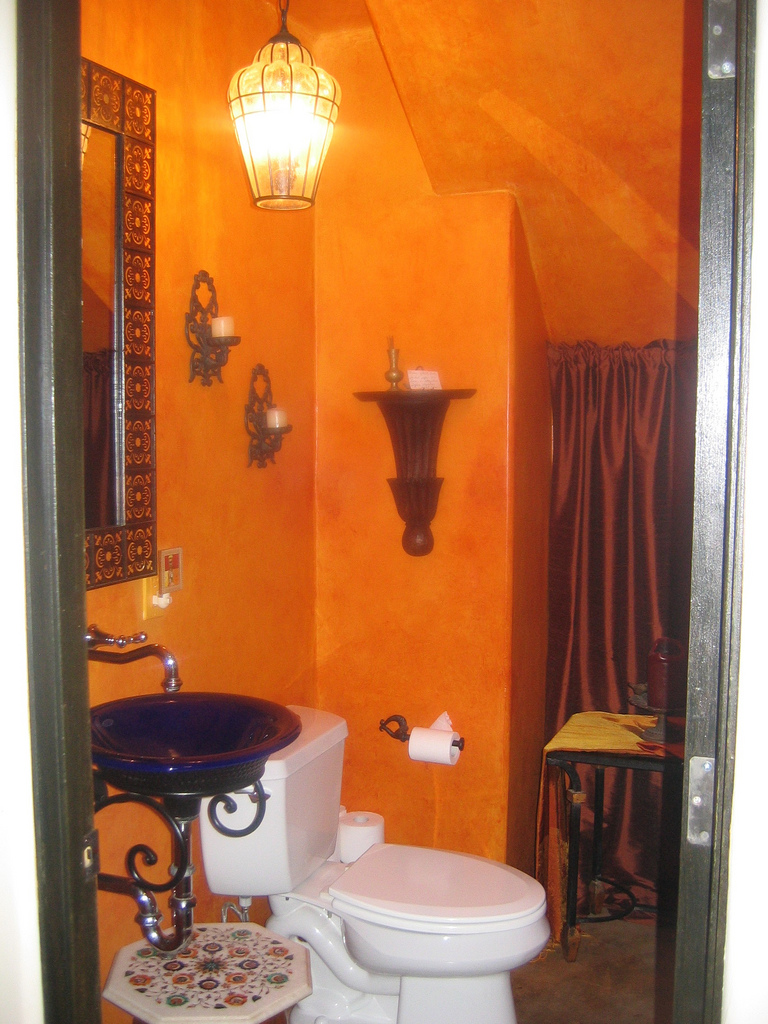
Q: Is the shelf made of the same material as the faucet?
A: No, the shelf is made of wood and the faucet is made of metal.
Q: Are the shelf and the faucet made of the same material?
A: No, the shelf is made of wood and the faucet is made of metal.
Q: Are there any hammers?
A: No, there are no hammers.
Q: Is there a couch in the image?
A: No, there are no couches.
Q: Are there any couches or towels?
A: No, there are no couches or towels.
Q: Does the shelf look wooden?
A: Yes, the shelf is wooden.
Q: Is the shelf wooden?
A: Yes, the shelf is wooden.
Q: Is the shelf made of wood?
A: Yes, the shelf is made of wood.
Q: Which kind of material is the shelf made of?
A: The shelf is made of wood.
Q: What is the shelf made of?
A: The shelf is made of wood.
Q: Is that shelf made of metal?
A: No, the shelf is made of wood.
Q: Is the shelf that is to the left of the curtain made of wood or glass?
A: The shelf is made of wood.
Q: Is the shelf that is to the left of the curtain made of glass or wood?
A: The shelf is made of wood.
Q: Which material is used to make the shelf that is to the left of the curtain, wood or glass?
A: The shelf is made of wood.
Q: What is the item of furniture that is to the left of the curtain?
A: The piece of furniture is a shelf.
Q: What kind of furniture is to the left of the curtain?
A: The piece of furniture is a shelf.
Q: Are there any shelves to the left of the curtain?
A: Yes, there is a shelf to the left of the curtain.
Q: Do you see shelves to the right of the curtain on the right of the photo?
A: No, the shelf is to the left of the curtain.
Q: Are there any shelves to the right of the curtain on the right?
A: No, the shelf is to the left of the curtain.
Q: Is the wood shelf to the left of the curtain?
A: Yes, the shelf is to the left of the curtain.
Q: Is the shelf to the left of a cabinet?
A: No, the shelf is to the left of the curtain.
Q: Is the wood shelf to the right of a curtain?
A: No, the shelf is to the left of a curtain.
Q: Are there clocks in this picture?
A: No, there are no clocks.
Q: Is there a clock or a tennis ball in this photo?
A: No, there are no clocks or tennis balls.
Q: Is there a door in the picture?
A: Yes, there is a door.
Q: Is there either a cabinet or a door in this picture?
A: Yes, there is a door.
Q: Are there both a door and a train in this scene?
A: No, there is a door but no trains.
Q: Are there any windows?
A: No, there are no windows.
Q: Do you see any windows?
A: No, there are no windows.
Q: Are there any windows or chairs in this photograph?
A: No, there are no windows or chairs.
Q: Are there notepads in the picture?
A: No, there are no notepads.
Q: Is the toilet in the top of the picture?
A: No, the toilet is in the bottom of the image.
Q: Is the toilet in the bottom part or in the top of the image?
A: The toilet is in the bottom of the image.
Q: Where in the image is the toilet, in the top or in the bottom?
A: The toilet is in the bottom of the image.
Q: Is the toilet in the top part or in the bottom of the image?
A: The toilet is in the bottom of the image.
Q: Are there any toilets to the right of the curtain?
A: No, the toilet is to the left of the curtain.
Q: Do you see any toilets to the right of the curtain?
A: No, the toilet is to the left of the curtain.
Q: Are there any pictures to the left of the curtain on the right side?
A: No, there is a toilet to the left of the curtain.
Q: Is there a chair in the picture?
A: No, there are no chairs.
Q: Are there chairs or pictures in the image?
A: No, there are no chairs or pictures.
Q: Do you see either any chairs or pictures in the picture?
A: No, there are no chairs or pictures.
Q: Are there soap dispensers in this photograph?
A: No, there are no soap dispensers.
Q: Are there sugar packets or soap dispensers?
A: No, there are no soap dispensers or sugar packets.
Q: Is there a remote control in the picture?
A: No, there are no remote controls.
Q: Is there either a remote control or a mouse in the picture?
A: No, there are no remote controls or computer mice.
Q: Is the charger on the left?
A: Yes, the charger is on the left of the image.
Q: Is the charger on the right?
A: No, the charger is on the left of the image.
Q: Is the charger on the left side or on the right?
A: The charger is on the left of the image.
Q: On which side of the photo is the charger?
A: The charger is on the left of the image.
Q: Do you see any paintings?
A: No, there are no paintings.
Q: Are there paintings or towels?
A: No, there are no paintings or towels.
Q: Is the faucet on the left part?
A: Yes, the faucet is on the left of the image.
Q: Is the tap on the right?
A: No, the tap is on the left of the image.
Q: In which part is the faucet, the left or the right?
A: The faucet is on the left of the image.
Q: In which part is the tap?
A: The tap is on the left of the image.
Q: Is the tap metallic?
A: Yes, the tap is metallic.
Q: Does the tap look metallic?
A: Yes, the tap is metallic.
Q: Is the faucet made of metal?
A: Yes, the faucet is made of metal.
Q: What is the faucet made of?
A: The faucet is made of metal.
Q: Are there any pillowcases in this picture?
A: No, there are no pillowcases.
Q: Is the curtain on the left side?
A: No, the curtain is on the right of the image.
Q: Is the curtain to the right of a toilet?
A: Yes, the curtain is to the right of a toilet.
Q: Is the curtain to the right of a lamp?
A: No, the curtain is to the right of a toilet.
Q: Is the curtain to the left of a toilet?
A: No, the curtain is to the right of a toilet.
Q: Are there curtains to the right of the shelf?
A: Yes, there is a curtain to the right of the shelf.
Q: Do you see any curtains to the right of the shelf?
A: Yes, there is a curtain to the right of the shelf.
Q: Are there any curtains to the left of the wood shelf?
A: No, the curtain is to the right of the shelf.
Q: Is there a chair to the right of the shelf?
A: No, there is a curtain to the right of the shelf.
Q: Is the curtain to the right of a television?
A: No, the curtain is to the right of the shelf.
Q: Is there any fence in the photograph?
A: No, there are no fences.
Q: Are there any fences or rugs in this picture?
A: No, there are no fences or rugs.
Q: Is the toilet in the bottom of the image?
A: Yes, the toilet is in the bottom of the image.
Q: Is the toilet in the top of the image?
A: No, the toilet is in the bottom of the image.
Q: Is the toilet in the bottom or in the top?
A: The toilet is in the bottom of the image.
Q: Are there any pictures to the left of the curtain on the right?
A: No, there is a toilet to the left of the curtain.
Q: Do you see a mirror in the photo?
A: Yes, there is a mirror.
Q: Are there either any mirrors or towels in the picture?
A: Yes, there is a mirror.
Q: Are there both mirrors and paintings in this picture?
A: No, there is a mirror but no paintings.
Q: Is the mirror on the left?
A: Yes, the mirror is on the left of the image.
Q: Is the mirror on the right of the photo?
A: No, the mirror is on the left of the image.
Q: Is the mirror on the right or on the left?
A: The mirror is on the left of the image.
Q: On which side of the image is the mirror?
A: The mirror is on the left of the image.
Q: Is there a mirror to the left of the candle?
A: Yes, there is a mirror to the left of the candle.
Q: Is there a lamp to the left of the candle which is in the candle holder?
A: No, there is a mirror to the left of the candle.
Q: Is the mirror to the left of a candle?
A: Yes, the mirror is to the left of a candle.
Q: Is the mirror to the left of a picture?
A: No, the mirror is to the left of a candle.